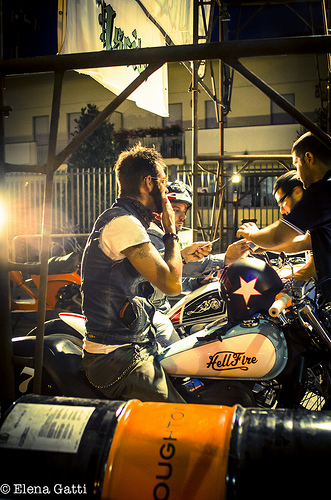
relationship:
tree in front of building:
[59, 97, 118, 228] [1, 1, 330, 284]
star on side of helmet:
[233, 276, 262, 303] [219, 256, 282, 324]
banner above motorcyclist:
[59, 7, 201, 118] [72, 126, 320, 405]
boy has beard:
[86, 145, 186, 401] [151, 175, 165, 215]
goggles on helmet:
[162, 182, 193, 195] [221, 261, 280, 314]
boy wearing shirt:
[86, 145, 186, 401] [78, 211, 153, 355]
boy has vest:
[86, 145, 186, 401] [98, 204, 142, 333]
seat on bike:
[27, 328, 81, 374] [9, 282, 328, 409]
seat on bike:
[27, 328, 81, 374] [21, 247, 306, 333]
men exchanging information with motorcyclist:
[235, 132, 329, 304] [79, 143, 188, 404]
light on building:
[229, 170, 242, 184] [3, 35, 329, 241]